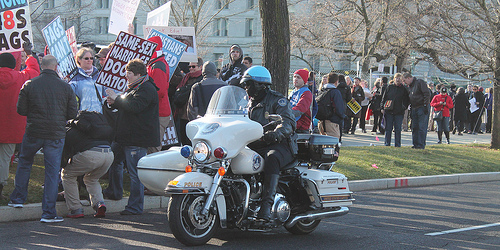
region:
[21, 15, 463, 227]
a demonstration against gay marriage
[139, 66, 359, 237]
a policeman on a motorcycle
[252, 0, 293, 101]
the tree behind the officer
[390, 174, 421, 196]
three red lines painted on the curb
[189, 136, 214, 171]
the headlight on the motorcycle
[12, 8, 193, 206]
a group of people holding picket signs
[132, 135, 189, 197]
the motorcycle's sidecar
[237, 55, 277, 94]
the officer's helmet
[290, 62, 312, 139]
a person in a red knit cap standing by the tree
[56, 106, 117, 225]
a man with a backpack bending over to pick something off the ground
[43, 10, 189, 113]
anti gay marriage protesters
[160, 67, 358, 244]
a police officer on a motorcycle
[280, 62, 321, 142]
man in red stocking cap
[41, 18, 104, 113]
woman in sunglasses holding a picket sign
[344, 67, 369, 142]
man holding a yellow sign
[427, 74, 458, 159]
women in red coat with a purse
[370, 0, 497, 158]
people under a leafless tree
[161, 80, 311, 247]
white police motorcycle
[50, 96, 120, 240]
man stooping to pick something up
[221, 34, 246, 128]
tall man in gray hoodie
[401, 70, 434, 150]
a person is standing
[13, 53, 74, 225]
a person is standing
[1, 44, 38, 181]
a person is standing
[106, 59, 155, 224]
a person is standing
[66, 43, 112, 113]
a person is standing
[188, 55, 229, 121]
a person is standing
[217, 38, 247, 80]
a person is standing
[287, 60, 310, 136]
a person is standing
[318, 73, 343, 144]
a person is standing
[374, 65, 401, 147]
a person is standing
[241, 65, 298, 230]
police officer on white motorcycle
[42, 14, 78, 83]
black sign that says fags can't repent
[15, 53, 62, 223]
bald man in black coat with one foot on the curb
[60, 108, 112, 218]
person in khaki pants crouching near curb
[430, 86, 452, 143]
woman in red coat and black hat texting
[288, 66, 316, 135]
person by tree wearing a red hat and blue scarf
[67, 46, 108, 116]
bloond woman in blue sweater wearing sunglasses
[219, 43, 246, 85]
tall man in black behind officer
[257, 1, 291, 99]
large tree trunk behind officer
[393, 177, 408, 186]
red stripes on the curb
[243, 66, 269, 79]
this is a helmet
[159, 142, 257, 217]
this is a motorbike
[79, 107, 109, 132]
this is a bag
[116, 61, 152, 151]
this is a man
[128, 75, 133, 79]
the man has a light skin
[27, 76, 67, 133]
this is a jacket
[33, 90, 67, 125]
the jacket is black in color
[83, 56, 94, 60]
this is a spectacle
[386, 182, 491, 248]
this is a road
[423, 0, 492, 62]
this is a tree